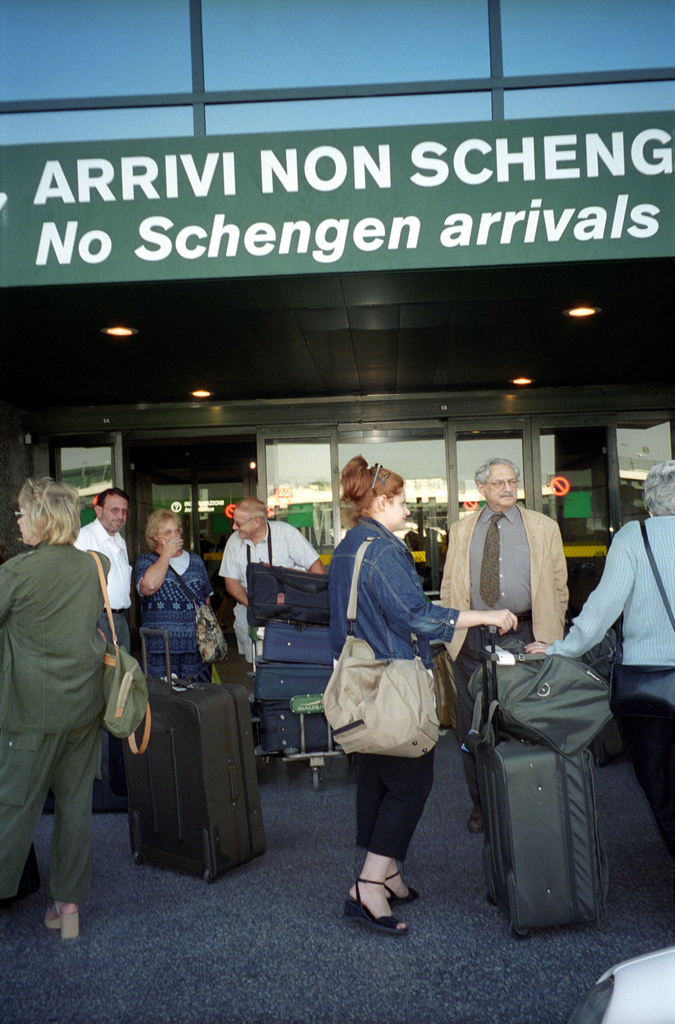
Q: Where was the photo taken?
A: An airport.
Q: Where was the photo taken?
A: At an airport.